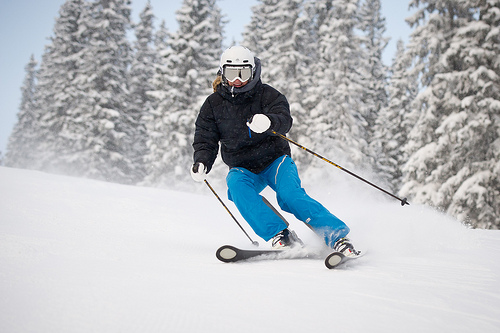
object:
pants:
[225, 156, 351, 240]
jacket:
[192, 90, 294, 173]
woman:
[189, 45, 363, 266]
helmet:
[217, 45, 257, 74]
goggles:
[223, 67, 251, 83]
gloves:
[244, 112, 274, 134]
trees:
[54, 22, 132, 170]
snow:
[157, 39, 186, 103]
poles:
[197, 166, 260, 246]